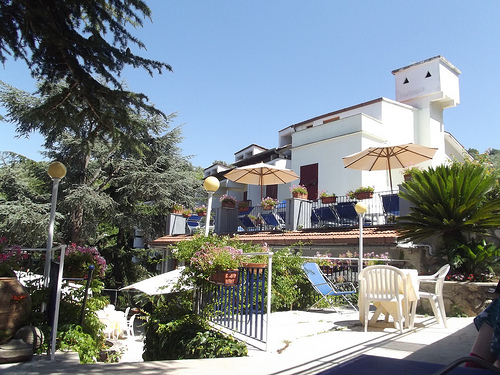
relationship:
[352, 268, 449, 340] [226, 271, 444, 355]
chairs on patio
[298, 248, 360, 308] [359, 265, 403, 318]
chair behind chair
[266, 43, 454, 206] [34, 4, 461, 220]
building in background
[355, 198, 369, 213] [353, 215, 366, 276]
globes on pole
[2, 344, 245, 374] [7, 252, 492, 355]
path in garden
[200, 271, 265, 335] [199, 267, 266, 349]
bars of bars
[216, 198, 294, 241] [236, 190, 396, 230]
chairs behind fence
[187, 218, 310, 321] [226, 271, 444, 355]
plants by patio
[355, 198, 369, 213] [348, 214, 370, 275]
globes on pole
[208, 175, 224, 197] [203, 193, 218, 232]
light on pole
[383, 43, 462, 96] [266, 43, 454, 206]
part of building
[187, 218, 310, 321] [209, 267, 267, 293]
plants in box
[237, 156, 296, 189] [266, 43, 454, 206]
umbrella next to building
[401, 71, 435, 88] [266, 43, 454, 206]
shapes on building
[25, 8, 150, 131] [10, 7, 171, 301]
tree in distance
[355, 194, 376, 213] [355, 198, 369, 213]
globes on globes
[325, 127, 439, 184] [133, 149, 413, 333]
umbrella by poolside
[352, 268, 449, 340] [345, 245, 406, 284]
chairs at table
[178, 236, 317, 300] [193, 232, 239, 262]
shrubbery with flowers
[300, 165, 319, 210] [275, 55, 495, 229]
door on building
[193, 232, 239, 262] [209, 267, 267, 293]
flowers in box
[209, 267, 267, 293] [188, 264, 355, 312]
box attached to railing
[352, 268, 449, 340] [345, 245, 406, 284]
chairs near table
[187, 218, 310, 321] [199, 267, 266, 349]
plants near bars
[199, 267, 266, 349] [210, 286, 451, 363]
bars on concrete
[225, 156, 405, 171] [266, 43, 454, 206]
umbrellas near building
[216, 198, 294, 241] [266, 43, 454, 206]
chairs near building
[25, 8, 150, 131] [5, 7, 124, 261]
tree on left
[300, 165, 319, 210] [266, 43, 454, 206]
door on building